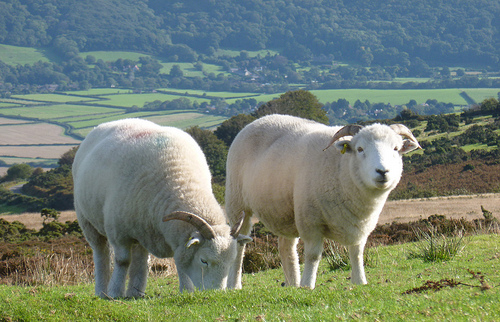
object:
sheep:
[72, 113, 423, 298]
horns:
[162, 211, 216, 240]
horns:
[322, 125, 363, 152]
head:
[323, 124, 422, 190]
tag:
[341, 143, 347, 155]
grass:
[0, 221, 500, 322]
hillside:
[0, 90, 499, 322]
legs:
[295, 216, 324, 289]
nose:
[375, 168, 389, 175]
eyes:
[357, 147, 363, 153]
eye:
[201, 258, 208, 265]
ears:
[334, 139, 352, 154]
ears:
[184, 239, 200, 249]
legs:
[107, 236, 134, 298]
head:
[162, 211, 253, 291]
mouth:
[374, 178, 390, 188]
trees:
[0, 0, 498, 272]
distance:
[0, 58, 497, 116]